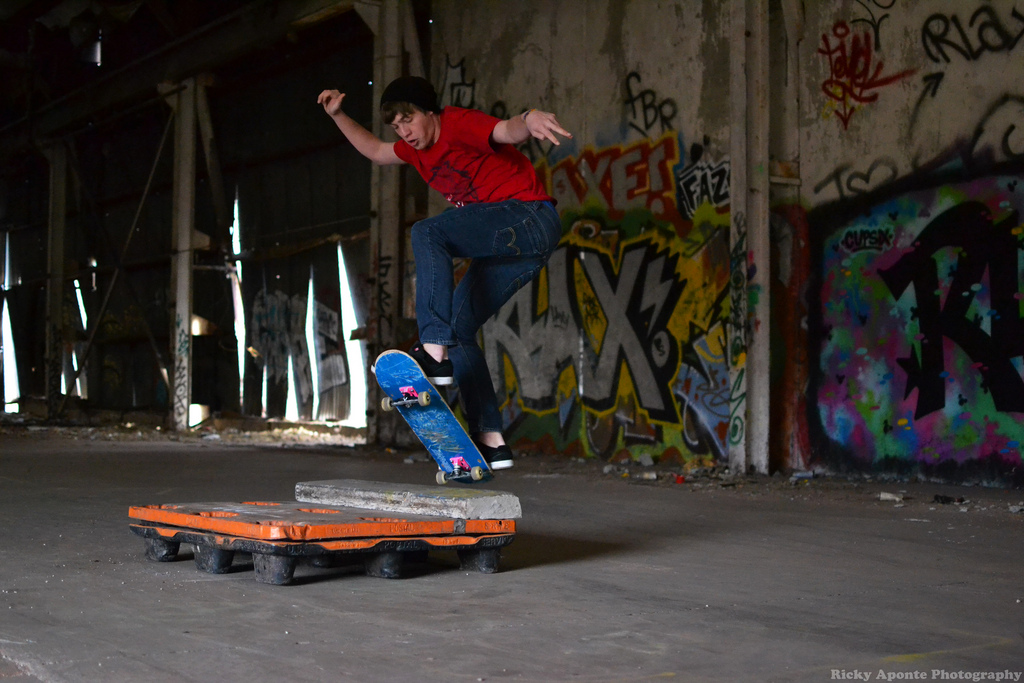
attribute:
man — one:
[323, 70, 585, 470]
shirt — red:
[379, 98, 546, 198]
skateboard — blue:
[346, 323, 506, 525]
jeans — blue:
[413, 202, 552, 417]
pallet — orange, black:
[131, 465, 549, 604]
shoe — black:
[397, 348, 464, 401]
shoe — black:
[474, 437, 516, 476]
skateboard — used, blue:
[208, 290, 602, 610]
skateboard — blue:
[348, 337, 498, 504]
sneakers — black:
[386, 329, 443, 381]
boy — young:
[309, 68, 569, 479]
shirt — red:
[376, 88, 536, 218]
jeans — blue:
[406, 193, 558, 442]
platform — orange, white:
[123, 448, 549, 602]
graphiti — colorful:
[477, 194, 763, 469]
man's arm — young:
[454, 90, 573, 158]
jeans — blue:
[410, 202, 571, 432]